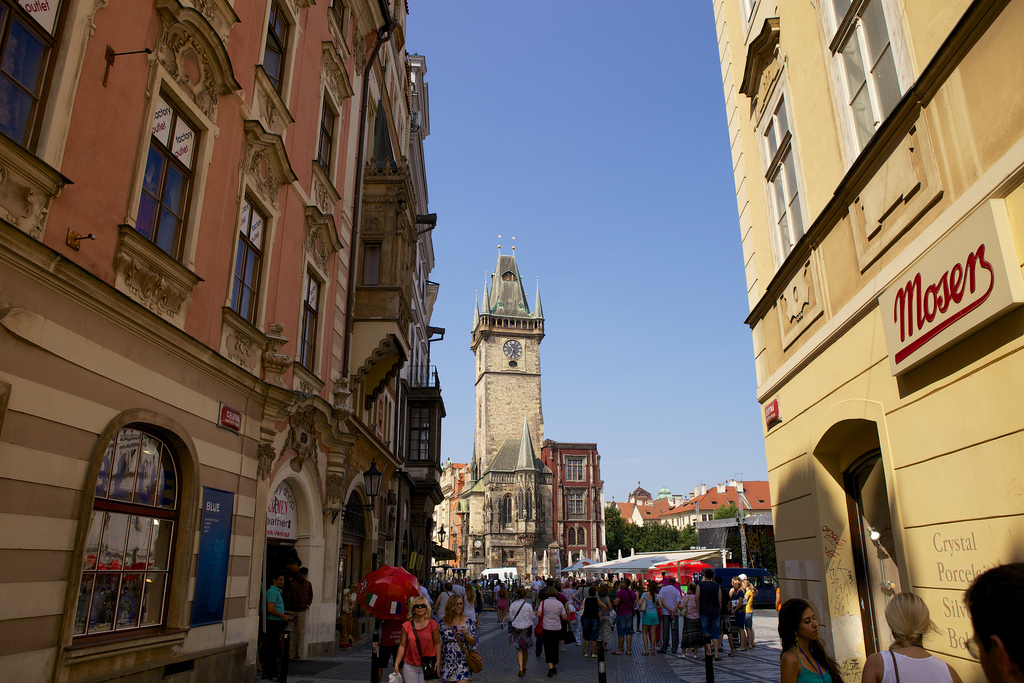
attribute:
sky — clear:
[402, 0, 760, 501]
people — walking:
[654, 582, 681, 656]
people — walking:
[612, 575, 641, 668]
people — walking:
[638, 582, 664, 649]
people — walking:
[607, 576, 636, 665]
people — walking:
[680, 583, 709, 656]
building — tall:
[470, 243, 535, 557]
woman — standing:
[775, 601, 837, 675]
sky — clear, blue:
[418, 9, 792, 532]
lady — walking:
[402, 591, 445, 678]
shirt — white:
[876, 648, 957, 680]